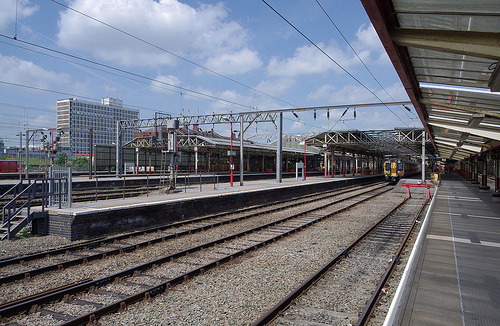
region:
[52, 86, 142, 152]
a multi-storey white building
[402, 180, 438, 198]
a small red bench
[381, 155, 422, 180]
a yellow train car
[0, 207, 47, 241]
a short set of steps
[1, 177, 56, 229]
dark grey stair railing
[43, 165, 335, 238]
a light grey railway platform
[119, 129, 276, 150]
railway station cover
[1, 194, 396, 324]
dark brown train tracks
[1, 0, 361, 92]
blue sky with white clouds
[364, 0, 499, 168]
a railway platform cover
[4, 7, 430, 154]
a sky with clouds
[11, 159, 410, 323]
a few tracks on the ground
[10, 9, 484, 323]
a subway downtown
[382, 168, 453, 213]
a red barricade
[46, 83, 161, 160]
a white building in the distance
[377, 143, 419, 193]
a yellow train in the distance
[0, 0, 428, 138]
some cables overhead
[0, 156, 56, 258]
a staircase on the left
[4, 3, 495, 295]
a scene outside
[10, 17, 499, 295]
scene during the day time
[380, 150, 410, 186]
the front of a train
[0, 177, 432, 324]
pairs of train tracks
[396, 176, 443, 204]
a red barrier on the tracks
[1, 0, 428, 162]
a cloudy blue sky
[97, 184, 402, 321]
gray gravel by the tracks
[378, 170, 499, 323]
a gray cement sidewalk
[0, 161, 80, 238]
a metal staircase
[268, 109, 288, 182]
a gray metal pole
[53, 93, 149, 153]
a large white building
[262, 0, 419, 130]
black wires in the sky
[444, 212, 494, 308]
White lines on platform.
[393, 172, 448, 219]
Red object on tracks.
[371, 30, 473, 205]
Overhang covering platform.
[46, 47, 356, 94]
Wires in the air above the tracks.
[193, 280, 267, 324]
Gravel in between and next to the tracks.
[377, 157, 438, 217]
Yellow train on the tracks.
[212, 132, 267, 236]
Red poles near the tracks.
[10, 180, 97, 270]
Stairs leading up to concrete standing area.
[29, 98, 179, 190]
Large building in distance.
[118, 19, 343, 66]
White clouds in the sky.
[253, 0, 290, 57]
part of the sky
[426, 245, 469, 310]
part of a floor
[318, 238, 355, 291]
part of a train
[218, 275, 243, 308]
part of a ground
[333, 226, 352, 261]
edge of a rail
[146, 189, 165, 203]
part of an edge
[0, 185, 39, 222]
part of a stair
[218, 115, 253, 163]
part of a post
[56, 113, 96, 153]
part of a building